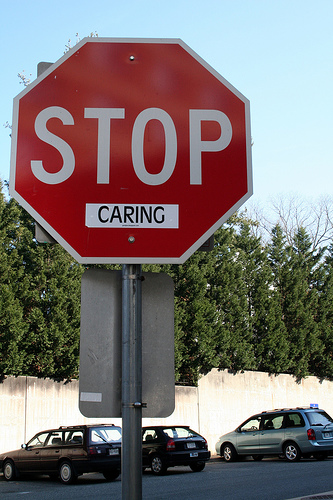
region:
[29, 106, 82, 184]
The S on the Stop sign.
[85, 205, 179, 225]
The white sticker on the stop sign.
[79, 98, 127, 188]
The letter T on the stop sign.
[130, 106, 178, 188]
The letter O on the stop sign.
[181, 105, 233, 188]
The letter P on the stop sign.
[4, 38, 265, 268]
The entire region around the stop sign.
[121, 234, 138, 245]
The bottom screw on the stop sign.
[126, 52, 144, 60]
The top screw on the stop sign.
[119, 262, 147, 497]
The pole the stop sign is mounted on.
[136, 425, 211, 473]
The small black car in the middle.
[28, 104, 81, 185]
a letter 'S' written in white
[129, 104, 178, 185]
a letter 'O' written in white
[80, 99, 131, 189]
a letter 'T' written in white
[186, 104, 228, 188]
a letter 'P' written in white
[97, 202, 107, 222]
a letter 'C' written in black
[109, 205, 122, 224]
a letter 'A' written in black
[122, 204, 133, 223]
a letter 'R' written in black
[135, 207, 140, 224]
a letter 'I' written in black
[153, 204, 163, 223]
a letter 'G' written in black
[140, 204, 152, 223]
a letter 'N' written in black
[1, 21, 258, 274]
red stop sign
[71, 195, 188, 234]
white and black sticker on red stop sign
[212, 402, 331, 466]
grey van in parking lot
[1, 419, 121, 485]
black station wagon in parking lot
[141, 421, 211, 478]
black hatchback car in parking lot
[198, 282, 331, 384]
row of green pine trees above stone wall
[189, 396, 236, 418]
stone wall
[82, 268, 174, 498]
metal pole with street sign attached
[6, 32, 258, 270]
red and white vandalized stop sign with sticker graffiti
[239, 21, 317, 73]
clear blue sky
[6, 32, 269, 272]
A red and white Stop sign.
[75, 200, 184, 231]
A white sticker that says "CARING"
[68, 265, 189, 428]
The back of a sign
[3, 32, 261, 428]
A stop sign on top of a backwards sign.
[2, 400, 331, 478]
Three cars parked in front of a white wall.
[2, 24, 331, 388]
Trees behind a white wall.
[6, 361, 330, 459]
A white wall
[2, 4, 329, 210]
Blue Sky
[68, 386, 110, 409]
A white label on the back of a sign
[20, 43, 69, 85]
A corner of a sign that is behind the Stop sign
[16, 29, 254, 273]
hexagonal stop sign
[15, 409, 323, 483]
parked cars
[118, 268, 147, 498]
metal signpost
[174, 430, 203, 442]
windshield wiper on the rear window of a black hatchback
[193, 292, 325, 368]
green pine trees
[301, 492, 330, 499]
manhole cover in the roadway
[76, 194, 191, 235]
sticker graffiti on a stop sign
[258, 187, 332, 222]
bare tree branches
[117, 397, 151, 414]
metal clamp holding sign to a metal post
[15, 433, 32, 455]
side view mirror on a parked car